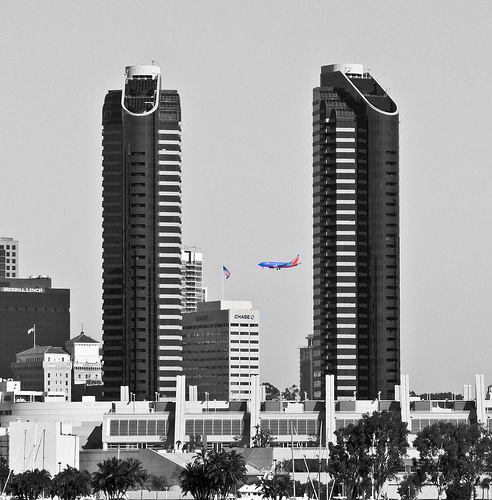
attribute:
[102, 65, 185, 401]
tower — big, alike, identical, black, skyscraper, large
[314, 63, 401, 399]
tower — identical, big, alike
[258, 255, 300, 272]
airplane — blue, red, flying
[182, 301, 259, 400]
building — chase, large, chase bank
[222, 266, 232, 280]
flag — american, part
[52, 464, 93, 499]
tree — palm tree, palm, in small group, deciduous, in a row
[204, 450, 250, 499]
tree — palm tree, palm, in small group, deciduous, in a row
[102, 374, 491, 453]
building — large, short, long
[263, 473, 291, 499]
tree — palm tree, palm, in small group, deciduous, in a row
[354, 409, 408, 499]
tree — deciduous, in a row, palm tree, palm, in small group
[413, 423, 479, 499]
tree — palm tree, palm, in small group, deciduous, in a row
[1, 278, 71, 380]
building — large, merril lynch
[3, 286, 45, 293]
label — merrill lynch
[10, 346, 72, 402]
building — smaller, small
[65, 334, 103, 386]
building — smaller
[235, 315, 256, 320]
logo — chase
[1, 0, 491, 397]
sky — part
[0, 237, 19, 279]
building — tall, large, multi story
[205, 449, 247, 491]
leaves — green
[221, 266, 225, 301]
pole — white colored